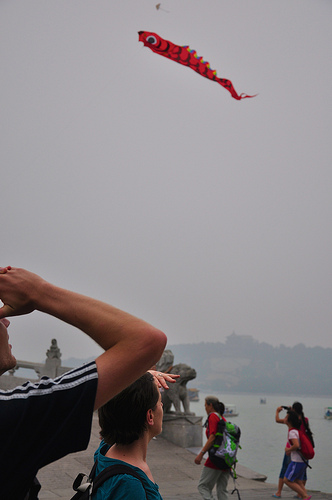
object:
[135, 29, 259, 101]
kite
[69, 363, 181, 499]
person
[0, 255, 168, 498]
person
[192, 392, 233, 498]
person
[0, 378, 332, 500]
street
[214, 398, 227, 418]
person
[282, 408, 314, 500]
person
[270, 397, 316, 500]
person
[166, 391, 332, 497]
ocean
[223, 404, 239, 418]
boat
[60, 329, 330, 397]
hill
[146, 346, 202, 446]
statue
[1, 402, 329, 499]
plaza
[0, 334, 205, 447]
wall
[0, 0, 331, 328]
sky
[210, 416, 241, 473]
backpack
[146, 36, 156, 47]
eye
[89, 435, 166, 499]
shirt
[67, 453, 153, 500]
backpack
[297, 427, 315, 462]
backpack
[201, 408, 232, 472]
shirt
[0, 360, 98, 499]
shirt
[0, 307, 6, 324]
eyes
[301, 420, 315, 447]
baby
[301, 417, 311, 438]
back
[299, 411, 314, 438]
pony tail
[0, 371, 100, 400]
stripes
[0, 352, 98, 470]
sleeve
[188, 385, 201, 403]
boat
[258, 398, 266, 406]
boat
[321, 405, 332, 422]
boat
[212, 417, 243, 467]
baby dress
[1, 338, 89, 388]
railing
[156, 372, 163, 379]
ring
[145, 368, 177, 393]
hand